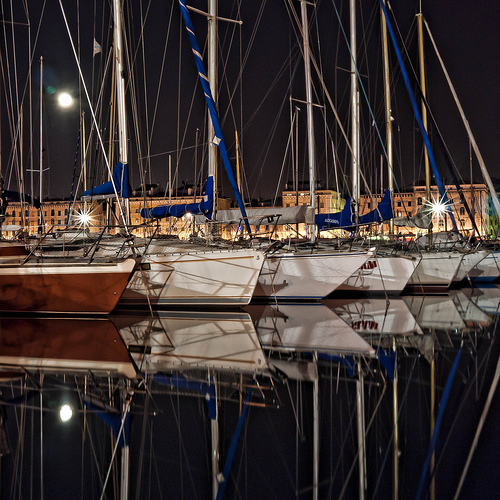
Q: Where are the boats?
A: Floating in the water at a dock.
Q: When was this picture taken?
A: At night.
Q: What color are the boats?
A: White and red.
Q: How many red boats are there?
A: One.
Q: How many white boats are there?
A: Six.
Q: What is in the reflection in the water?
A: The boats.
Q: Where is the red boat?
A: The first one on the left.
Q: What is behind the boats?
A: Buildings.